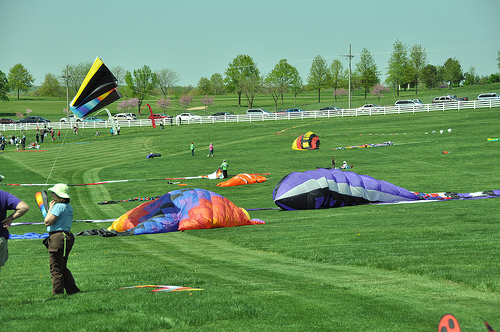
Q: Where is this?
A: This is at the field.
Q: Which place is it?
A: It is a field.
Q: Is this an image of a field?
A: Yes, it is showing a field.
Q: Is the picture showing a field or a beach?
A: It is showing a field.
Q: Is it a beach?
A: No, it is a field.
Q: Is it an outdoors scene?
A: Yes, it is outdoors.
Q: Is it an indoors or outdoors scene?
A: It is outdoors.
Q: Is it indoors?
A: No, it is outdoors.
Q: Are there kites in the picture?
A: Yes, there is a kite.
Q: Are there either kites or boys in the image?
A: Yes, there is a kite.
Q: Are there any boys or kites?
A: Yes, there is a kite.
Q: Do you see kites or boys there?
A: Yes, there is a kite.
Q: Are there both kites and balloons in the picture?
A: Yes, there are both a kite and a balloon.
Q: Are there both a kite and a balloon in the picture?
A: Yes, there are both a kite and a balloon.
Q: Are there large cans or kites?
A: Yes, there is a large kite.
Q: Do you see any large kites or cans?
A: Yes, there is a large kite.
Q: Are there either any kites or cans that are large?
A: Yes, the kite is large.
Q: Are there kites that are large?
A: Yes, there is a large kite.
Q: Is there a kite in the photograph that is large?
A: Yes, there is a kite that is large.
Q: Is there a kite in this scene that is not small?
A: Yes, there is a large kite.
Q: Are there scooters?
A: No, there are no scooters.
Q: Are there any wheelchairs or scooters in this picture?
A: No, there are no scooters or wheelchairs.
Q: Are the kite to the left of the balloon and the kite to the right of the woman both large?
A: Yes, both the kite and the kite are large.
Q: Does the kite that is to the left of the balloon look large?
A: Yes, the kite is large.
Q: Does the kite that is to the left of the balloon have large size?
A: Yes, the kite is large.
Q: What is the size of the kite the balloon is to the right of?
A: The kite is large.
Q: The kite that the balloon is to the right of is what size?
A: The kite is large.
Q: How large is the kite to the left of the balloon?
A: The kite is large.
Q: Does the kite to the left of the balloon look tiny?
A: No, the kite is large.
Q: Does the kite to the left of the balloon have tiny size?
A: No, the kite is large.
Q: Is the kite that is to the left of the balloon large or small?
A: The kite is large.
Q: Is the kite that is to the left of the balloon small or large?
A: The kite is large.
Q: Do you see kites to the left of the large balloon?
A: Yes, there is a kite to the left of the balloon.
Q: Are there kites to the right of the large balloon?
A: No, the kite is to the left of the balloon.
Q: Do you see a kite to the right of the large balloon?
A: No, the kite is to the left of the balloon.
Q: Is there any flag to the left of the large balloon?
A: No, there is a kite to the left of the balloon.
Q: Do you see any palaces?
A: No, there are no palaces.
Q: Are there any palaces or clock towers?
A: No, there are no palaces or clock towers.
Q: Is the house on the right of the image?
A: Yes, the house is on the right of the image.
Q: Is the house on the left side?
A: No, the house is on the right of the image.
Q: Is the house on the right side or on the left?
A: The house is on the right of the image.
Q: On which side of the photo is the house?
A: The house is on the right of the image.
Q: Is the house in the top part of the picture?
A: Yes, the house is in the top of the image.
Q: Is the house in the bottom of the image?
A: No, the house is in the top of the image.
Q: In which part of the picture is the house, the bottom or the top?
A: The house is in the top of the image.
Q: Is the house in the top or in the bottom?
A: The house is in the top of the image.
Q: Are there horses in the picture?
A: No, there are no horses.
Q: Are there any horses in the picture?
A: No, there are no horses.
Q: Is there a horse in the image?
A: No, there are no horses.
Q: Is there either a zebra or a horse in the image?
A: No, there are no horses or zebras.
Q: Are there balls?
A: No, there are no balls.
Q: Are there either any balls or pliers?
A: No, there are no balls or pliers.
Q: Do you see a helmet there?
A: No, there are no helmets.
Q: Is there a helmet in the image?
A: No, there are no helmets.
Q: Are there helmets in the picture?
A: No, there are no helmets.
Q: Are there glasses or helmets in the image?
A: No, there are no helmets or glasses.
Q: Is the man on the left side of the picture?
A: Yes, the man is on the left of the image.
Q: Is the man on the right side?
A: No, the man is on the left of the image.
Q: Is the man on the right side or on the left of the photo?
A: The man is on the left of the image.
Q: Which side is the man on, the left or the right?
A: The man is on the left of the image.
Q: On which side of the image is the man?
A: The man is on the left of the image.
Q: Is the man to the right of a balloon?
A: No, the man is to the left of a balloon.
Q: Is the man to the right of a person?
A: No, the man is to the left of a person.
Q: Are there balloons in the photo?
A: Yes, there is a balloon.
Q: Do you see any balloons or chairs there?
A: Yes, there is a balloon.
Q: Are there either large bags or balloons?
A: Yes, there is a large balloon.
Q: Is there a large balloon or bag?
A: Yes, there is a large balloon.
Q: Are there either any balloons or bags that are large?
A: Yes, the balloon is large.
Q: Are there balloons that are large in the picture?
A: Yes, there is a large balloon.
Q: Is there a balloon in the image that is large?
A: Yes, there is a balloon that is large.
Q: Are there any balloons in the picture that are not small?
A: Yes, there is a large balloon.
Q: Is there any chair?
A: No, there are no chairs.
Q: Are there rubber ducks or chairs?
A: No, there are no chairs or rubber ducks.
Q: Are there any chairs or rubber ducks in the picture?
A: No, there are no chairs or rubber ducks.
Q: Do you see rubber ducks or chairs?
A: No, there are no chairs or rubber ducks.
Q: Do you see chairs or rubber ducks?
A: No, there are no chairs or rubber ducks.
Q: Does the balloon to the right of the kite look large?
A: Yes, the balloon is large.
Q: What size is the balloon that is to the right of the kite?
A: The balloon is large.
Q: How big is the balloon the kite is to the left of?
A: The balloon is large.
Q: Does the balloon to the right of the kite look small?
A: No, the balloon is large.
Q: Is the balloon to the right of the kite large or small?
A: The balloon is large.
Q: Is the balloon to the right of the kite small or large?
A: The balloon is large.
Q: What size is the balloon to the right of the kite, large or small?
A: The balloon is large.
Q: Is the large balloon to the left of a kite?
A: No, the balloon is to the right of a kite.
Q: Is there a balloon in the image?
A: Yes, there is a balloon.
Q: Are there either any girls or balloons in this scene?
A: Yes, there is a balloon.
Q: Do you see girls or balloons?
A: Yes, there is a balloon.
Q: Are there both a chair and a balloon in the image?
A: No, there is a balloon but no chairs.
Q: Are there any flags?
A: No, there are no flags.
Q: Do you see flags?
A: No, there are no flags.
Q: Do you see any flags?
A: No, there are no flags.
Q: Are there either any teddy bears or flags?
A: No, there are no flags or teddy bears.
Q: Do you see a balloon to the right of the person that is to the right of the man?
A: Yes, there is a balloon to the right of the person.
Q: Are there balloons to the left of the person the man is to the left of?
A: No, the balloon is to the right of the person.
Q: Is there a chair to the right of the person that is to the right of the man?
A: No, there is a balloon to the right of the person.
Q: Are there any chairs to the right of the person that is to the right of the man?
A: No, there is a balloon to the right of the person.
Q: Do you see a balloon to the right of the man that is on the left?
A: Yes, there is a balloon to the right of the man.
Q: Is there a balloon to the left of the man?
A: No, the balloon is to the right of the man.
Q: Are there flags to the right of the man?
A: No, there is a balloon to the right of the man.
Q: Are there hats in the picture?
A: Yes, there is a hat.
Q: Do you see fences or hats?
A: Yes, there is a hat.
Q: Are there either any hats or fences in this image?
A: Yes, there is a hat.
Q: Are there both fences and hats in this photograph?
A: Yes, there are both a hat and a fence.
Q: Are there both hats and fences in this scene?
A: Yes, there are both a hat and a fence.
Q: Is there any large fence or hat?
A: Yes, there is a large hat.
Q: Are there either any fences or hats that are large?
A: Yes, the hat is large.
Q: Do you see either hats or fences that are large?
A: Yes, the hat is large.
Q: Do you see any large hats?
A: Yes, there is a large hat.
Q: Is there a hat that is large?
A: Yes, there is a hat that is large.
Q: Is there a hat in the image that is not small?
A: Yes, there is a large hat.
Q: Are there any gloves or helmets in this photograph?
A: No, there are no helmets or gloves.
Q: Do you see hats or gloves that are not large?
A: No, there is a hat but it is large.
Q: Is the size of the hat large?
A: Yes, the hat is large.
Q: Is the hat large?
A: Yes, the hat is large.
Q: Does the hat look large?
A: Yes, the hat is large.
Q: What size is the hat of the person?
A: The hat is large.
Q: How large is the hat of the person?
A: The hat is large.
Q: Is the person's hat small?
A: No, the hat is large.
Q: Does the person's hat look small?
A: No, the hat is large.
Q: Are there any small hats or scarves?
A: No, there is a hat but it is large.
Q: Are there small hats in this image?
A: No, there is a hat but it is large.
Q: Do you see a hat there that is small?
A: No, there is a hat but it is large.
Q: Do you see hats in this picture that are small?
A: No, there is a hat but it is large.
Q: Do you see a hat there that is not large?
A: No, there is a hat but it is large.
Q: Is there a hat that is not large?
A: No, there is a hat but it is large.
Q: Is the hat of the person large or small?
A: The hat is large.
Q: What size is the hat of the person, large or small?
A: The hat is large.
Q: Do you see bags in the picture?
A: No, there are no bags.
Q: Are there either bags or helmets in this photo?
A: No, there are no bags or helmets.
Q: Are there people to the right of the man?
A: Yes, there is a person to the right of the man.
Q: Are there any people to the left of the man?
A: No, the person is to the right of the man.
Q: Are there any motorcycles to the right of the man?
A: No, there is a person to the right of the man.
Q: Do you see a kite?
A: Yes, there is a kite.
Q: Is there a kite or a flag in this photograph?
A: Yes, there is a kite.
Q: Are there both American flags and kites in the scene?
A: No, there is a kite but no American flags.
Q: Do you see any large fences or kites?
A: Yes, there is a large kite.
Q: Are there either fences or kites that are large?
A: Yes, the kite is large.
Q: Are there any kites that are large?
A: Yes, there is a large kite.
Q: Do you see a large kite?
A: Yes, there is a large kite.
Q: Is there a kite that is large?
A: Yes, there is a kite that is large.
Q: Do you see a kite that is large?
A: Yes, there is a kite that is large.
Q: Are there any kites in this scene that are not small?
A: Yes, there is a large kite.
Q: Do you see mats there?
A: No, there are no mats.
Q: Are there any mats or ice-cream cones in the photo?
A: No, there are no mats or ice-cream cones.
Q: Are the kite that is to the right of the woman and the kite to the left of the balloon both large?
A: Yes, both the kite and the kite are large.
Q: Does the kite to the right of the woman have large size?
A: Yes, the kite is large.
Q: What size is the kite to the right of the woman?
A: The kite is large.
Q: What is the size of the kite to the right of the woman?
A: The kite is large.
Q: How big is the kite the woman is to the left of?
A: The kite is large.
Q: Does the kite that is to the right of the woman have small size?
A: No, the kite is large.